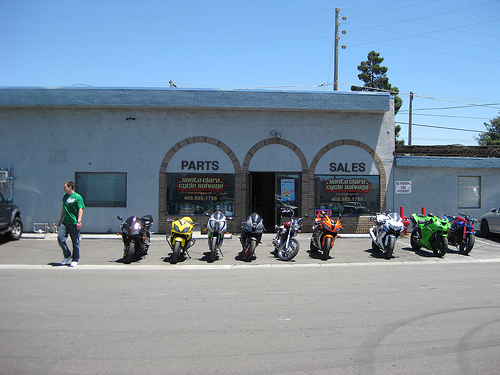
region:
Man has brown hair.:
[49, 175, 96, 202]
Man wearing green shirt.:
[56, 194, 91, 224]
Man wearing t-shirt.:
[53, 194, 109, 231]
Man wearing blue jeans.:
[37, 221, 105, 268]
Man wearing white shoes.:
[48, 251, 97, 284]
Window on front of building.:
[66, 164, 142, 199]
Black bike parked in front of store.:
[112, 208, 179, 299]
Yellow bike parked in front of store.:
[159, 200, 197, 287]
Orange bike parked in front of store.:
[304, 205, 334, 249]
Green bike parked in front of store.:
[421, 196, 451, 271]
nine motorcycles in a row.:
[107, 207, 485, 264]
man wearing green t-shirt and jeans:
[47, 178, 89, 270]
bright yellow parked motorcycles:
[160, 213, 202, 267]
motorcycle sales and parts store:
[150, 133, 388, 238]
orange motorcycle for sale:
[304, 205, 346, 262]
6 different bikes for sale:
[114, 205, 346, 268]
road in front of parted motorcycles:
[107, 210, 477, 363]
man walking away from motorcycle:
[49, 173, 155, 271]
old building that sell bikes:
[15, 84, 403, 262]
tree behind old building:
[4, 47, 401, 239]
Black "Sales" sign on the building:
[324, 160, 370, 177]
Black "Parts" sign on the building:
[175, 155, 222, 175]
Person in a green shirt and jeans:
[47, 175, 94, 272]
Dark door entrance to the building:
[245, 174, 277, 227]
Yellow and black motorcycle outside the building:
[165, 212, 198, 263]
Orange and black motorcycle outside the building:
[310, 208, 345, 263]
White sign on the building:
[395, 180, 412, 192]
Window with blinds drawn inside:
[457, 175, 484, 211]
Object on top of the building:
[162, 75, 182, 91]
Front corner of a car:
[0, 170, 27, 248]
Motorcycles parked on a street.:
[116, 214, 476, 257]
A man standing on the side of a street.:
[56, 180, 83, 268]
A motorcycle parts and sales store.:
[1, 87, 393, 234]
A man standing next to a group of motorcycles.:
[57, 180, 342, 267]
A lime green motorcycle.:
[408, 210, 453, 260]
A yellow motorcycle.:
[164, 217, 196, 262]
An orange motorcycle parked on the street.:
[310, 212, 343, 260]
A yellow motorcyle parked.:
[166, 216, 196, 262]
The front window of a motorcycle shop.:
[168, 173, 235, 219]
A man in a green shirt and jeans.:
[57, 180, 84, 267]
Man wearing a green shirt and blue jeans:
[54, 179, 86, 272]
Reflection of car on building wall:
[9, 175, 48, 232]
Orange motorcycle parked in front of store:
[305, 199, 345, 261]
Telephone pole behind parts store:
[310, 5, 360, 92]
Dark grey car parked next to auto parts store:
[0, 178, 27, 253]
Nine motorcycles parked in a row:
[112, 205, 480, 261]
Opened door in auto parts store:
[247, 168, 282, 230]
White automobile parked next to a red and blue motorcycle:
[448, 198, 498, 264]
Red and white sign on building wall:
[391, 180, 411, 196]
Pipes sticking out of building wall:
[25, 217, 64, 242]